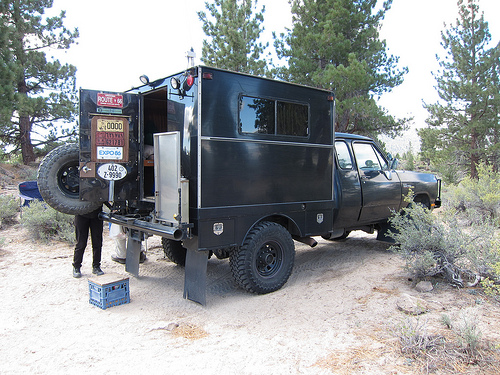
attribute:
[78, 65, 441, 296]
truck — broken, black, unlocked, parked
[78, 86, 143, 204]
door — open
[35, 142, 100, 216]
tire — black, hanging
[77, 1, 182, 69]
sky — clear, blue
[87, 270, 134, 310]
crate — blue, plastic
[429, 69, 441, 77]
leaves — green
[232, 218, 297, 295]
wheel — black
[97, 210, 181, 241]
pipe — black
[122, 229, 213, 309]
mudflaps — black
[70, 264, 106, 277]
shoes — black